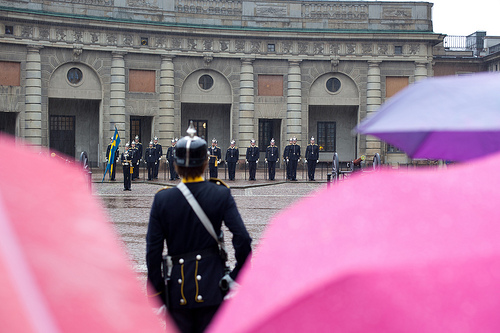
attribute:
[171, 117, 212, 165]
hat — black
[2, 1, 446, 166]
building — tall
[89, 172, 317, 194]
lines — white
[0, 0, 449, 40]
trimming — aqua blue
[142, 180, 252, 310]
jacket — black 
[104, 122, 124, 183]
flag — large, blue, yellow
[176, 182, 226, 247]
strap — white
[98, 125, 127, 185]
flag — blue, yellow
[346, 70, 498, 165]
umbrella — purple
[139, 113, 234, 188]
hat — shiny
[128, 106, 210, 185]
hat — black, shiny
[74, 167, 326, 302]
grounds — wet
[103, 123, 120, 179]
flag — YELLOW , BLUE 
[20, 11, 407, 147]
building — stone wash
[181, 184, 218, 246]
sash — white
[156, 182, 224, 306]
jacket — black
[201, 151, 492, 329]
umbrella top — pink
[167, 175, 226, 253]
strap — white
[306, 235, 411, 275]
object — pink